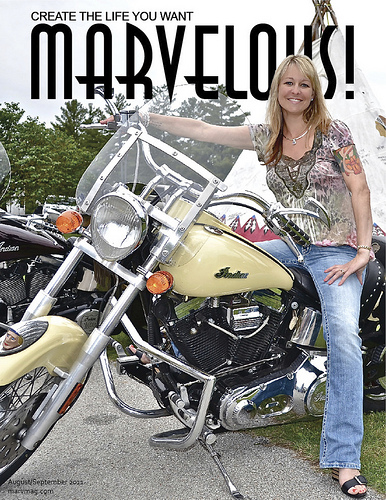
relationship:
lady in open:
[133, 48, 374, 409] [217, 30, 337, 150]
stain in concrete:
[56, 395, 125, 443] [74, 418, 135, 479]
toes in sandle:
[361, 488, 369, 492] [327, 465, 381, 497]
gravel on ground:
[96, 437, 113, 445] [74, 418, 135, 479]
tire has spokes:
[2, 366, 64, 465] [18, 371, 55, 401]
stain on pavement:
[56, 395, 125, 443] [62, 402, 131, 468]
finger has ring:
[316, 239, 367, 295] [336, 256, 355, 279]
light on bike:
[142, 245, 201, 293] [1, 127, 319, 498]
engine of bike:
[140, 224, 326, 403] [1, 127, 319, 498]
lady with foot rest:
[99, 55, 372, 499] [142, 342, 328, 432]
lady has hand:
[99, 55, 372, 499] [268, 247, 371, 317]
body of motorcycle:
[180, 210, 296, 308] [1, 127, 319, 498]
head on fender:
[104, 144, 184, 256] [2, 272, 162, 382]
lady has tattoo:
[99, 55, 372, 499] [310, 143, 369, 210]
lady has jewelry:
[99, 55, 372, 499] [264, 114, 319, 162]